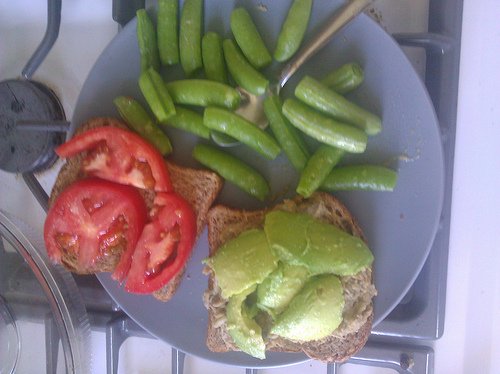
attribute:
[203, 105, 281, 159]
greenbean — cut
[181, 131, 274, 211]
green bean — cut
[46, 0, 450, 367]
plate — white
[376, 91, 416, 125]
plate — white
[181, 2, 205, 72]
green bean — cut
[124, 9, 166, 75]
bean — cut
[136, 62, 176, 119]
green bean — cut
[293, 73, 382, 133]
green bean — cut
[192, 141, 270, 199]
green bean — cut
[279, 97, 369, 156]
green bean — cut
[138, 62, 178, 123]
green bean — cut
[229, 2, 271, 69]
green bean — cut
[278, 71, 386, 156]
greens — on top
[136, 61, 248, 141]
greens — on top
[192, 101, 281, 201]
greens — on top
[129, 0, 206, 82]
greens — on top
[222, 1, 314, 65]
greens — on top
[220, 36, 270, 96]
green bean — cut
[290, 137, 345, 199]
bean — cut, green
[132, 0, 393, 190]
green beans — cut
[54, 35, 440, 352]
plate — blue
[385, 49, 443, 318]
plate — white